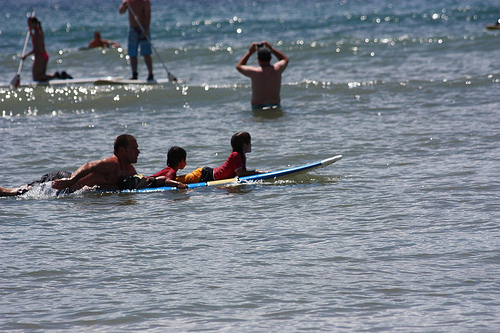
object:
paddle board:
[24, 63, 164, 104]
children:
[149, 133, 297, 173]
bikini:
[32, 31, 51, 63]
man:
[113, 0, 158, 82]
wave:
[0, 75, 499, 115]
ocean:
[0, 1, 499, 331]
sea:
[250, 94, 444, 201]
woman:
[14, 12, 51, 89]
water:
[0, 1, 497, 329]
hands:
[247, 40, 273, 53]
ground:
[391, 125, 440, 155]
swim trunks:
[127, 25, 153, 56]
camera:
[253, 40, 270, 51]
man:
[46, 128, 131, 186]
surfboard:
[7, 179, 343, 201]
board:
[94, 76, 182, 86]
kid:
[134, 147, 189, 191]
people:
[22, 3, 281, 178]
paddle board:
[45, 153, 348, 195]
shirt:
[213, 152, 247, 180]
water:
[340, 293, 499, 326]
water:
[252, 207, 421, 309]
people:
[0, 121, 277, 196]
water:
[184, 200, 235, 297]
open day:
[3, 2, 498, 330]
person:
[13, 9, 75, 85]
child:
[171, 117, 269, 191]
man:
[239, 40, 288, 116]